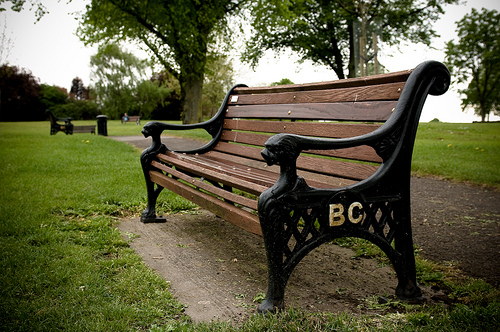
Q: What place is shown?
A: It is a park.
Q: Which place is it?
A: It is a park.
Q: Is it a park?
A: Yes, it is a park.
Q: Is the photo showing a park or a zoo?
A: It is showing a park.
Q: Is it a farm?
A: No, it is a park.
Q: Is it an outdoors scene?
A: Yes, it is outdoors.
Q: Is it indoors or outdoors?
A: It is outdoors.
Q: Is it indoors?
A: No, it is outdoors.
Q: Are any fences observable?
A: No, there are no fences.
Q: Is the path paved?
A: Yes, the path is paved.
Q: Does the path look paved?
A: Yes, the path is paved.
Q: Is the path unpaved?
A: No, the path is paved.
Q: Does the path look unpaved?
A: No, the path is paved.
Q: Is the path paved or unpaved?
A: The path is paved.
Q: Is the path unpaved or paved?
A: The path is paved.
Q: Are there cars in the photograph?
A: No, there are no cars.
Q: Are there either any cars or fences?
A: No, there are no cars or fences.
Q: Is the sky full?
A: Yes, the sky is full.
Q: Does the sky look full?
A: Yes, the sky is full.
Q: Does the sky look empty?
A: No, the sky is full.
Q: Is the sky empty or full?
A: The sky is full.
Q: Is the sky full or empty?
A: The sky is full.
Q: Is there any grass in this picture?
A: Yes, there is grass.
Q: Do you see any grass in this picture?
A: Yes, there is grass.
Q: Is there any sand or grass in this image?
A: Yes, there is grass.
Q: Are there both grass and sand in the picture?
A: No, there is grass but no sand.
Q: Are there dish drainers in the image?
A: No, there are no dish drainers.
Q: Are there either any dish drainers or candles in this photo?
A: No, there are no dish drainers or candles.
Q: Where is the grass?
A: The grass is in the field.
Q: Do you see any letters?
A: Yes, there are letters.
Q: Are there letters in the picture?
A: Yes, there are letters.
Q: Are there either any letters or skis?
A: Yes, there are letters.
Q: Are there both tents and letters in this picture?
A: No, there are letters but no tents.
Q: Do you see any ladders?
A: No, there are no ladders.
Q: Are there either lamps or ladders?
A: No, there are no ladders or lamps.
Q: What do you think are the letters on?
A: The letters are on the bench.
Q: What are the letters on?
A: The letters are on the bench.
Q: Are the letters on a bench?
A: Yes, the letters are on a bench.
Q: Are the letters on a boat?
A: No, the letters are on a bench.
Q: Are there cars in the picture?
A: No, there are no cars.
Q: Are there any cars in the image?
A: No, there are no cars.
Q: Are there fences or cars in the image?
A: No, there are no cars or fences.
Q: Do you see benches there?
A: Yes, there is a bench.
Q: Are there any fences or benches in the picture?
A: Yes, there is a bench.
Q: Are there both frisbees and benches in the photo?
A: No, there is a bench but no frisbees.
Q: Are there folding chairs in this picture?
A: No, there are no folding chairs.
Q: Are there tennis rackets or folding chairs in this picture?
A: No, there are no folding chairs or tennis rackets.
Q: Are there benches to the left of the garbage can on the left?
A: Yes, there is a bench to the left of the garbage can.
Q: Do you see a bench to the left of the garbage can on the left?
A: Yes, there is a bench to the left of the garbage can.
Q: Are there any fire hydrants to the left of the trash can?
A: No, there is a bench to the left of the trash can.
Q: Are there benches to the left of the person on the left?
A: Yes, there is a bench to the left of the person.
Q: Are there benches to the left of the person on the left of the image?
A: Yes, there is a bench to the left of the person.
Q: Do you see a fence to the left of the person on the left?
A: No, there is a bench to the left of the person.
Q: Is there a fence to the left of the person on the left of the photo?
A: No, there is a bench to the left of the person.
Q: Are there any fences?
A: No, there are no fences.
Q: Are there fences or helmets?
A: No, there are no fences or helmets.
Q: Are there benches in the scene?
A: Yes, there is a bench.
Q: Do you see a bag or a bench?
A: Yes, there is a bench.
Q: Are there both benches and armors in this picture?
A: No, there is a bench but no armors.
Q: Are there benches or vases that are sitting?
A: Yes, the bench is sitting.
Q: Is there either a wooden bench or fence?
A: Yes, there is a wood bench.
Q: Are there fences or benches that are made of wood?
A: Yes, the bench is made of wood.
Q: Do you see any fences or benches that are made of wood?
A: Yes, the bench is made of wood.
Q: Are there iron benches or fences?
A: Yes, there is an iron bench.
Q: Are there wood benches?
A: Yes, there is a bench that is made of wood.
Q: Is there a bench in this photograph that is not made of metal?
A: Yes, there is a bench that is made of wood.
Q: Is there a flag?
A: No, there are no flags.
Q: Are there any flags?
A: No, there are no flags.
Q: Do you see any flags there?
A: No, there are no flags.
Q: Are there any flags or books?
A: No, there are no flags or books.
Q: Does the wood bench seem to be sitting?
A: Yes, the bench is sitting.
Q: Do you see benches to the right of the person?
A: Yes, there is a bench to the right of the person.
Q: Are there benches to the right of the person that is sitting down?
A: Yes, there is a bench to the right of the person.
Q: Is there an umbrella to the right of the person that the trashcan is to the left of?
A: No, there is a bench to the right of the person.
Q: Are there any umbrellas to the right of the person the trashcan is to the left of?
A: No, there is a bench to the right of the person.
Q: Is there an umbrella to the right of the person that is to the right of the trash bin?
A: No, there is a bench to the right of the person.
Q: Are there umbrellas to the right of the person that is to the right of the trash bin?
A: No, there is a bench to the right of the person.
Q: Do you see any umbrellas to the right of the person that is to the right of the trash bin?
A: No, there is a bench to the right of the person.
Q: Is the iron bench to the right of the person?
A: Yes, the bench is to the right of the person.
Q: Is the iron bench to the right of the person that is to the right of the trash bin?
A: Yes, the bench is to the right of the person.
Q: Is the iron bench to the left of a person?
A: No, the bench is to the right of a person.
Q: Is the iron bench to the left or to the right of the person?
A: The bench is to the right of the person.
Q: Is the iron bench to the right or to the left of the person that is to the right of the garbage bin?
A: The bench is to the right of the person.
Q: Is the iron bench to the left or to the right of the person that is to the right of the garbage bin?
A: The bench is to the right of the person.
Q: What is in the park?
A: The bench is in the park.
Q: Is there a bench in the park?
A: Yes, there is a bench in the park.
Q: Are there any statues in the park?
A: No, there is a bench in the park.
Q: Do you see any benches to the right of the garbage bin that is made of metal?
A: Yes, there is a bench to the right of the garbage bin.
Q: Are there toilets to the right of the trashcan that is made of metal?
A: No, there is a bench to the right of the trashcan.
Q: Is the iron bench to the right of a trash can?
A: Yes, the bench is to the right of a trash can.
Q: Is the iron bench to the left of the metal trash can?
A: No, the bench is to the right of the trashcan.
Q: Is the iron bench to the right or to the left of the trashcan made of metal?
A: The bench is to the right of the trash bin.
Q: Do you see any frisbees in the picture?
A: No, there are no frisbees.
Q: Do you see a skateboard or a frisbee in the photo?
A: No, there are no frisbees or skateboards.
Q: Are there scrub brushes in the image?
A: No, there are no scrub brushes.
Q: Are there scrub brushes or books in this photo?
A: No, there are no scrub brushes or books.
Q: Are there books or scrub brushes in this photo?
A: No, there are no scrub brushes or books.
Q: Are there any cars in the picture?
A: No, there are no cars.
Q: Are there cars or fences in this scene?
A: No, there are no cars or fences.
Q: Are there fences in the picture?
A: No, there are no fences.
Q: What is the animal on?
A: The animal is on the bench.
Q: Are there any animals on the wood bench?
A: Yes, there is an animal on the bench.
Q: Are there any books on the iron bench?
A: No, there is an animal on the bench.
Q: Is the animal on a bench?
A: Yes, the animal is on a bench.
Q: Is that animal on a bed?
A: No, the animal is on a bench.